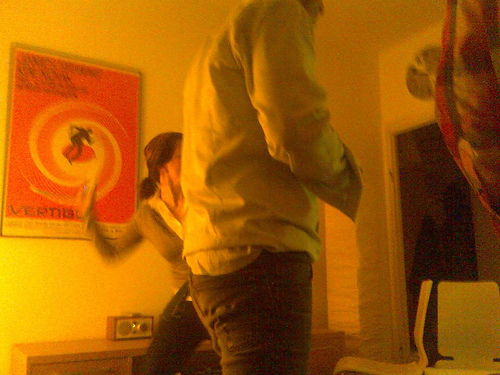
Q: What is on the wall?
A: Poster.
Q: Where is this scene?
A: Living room.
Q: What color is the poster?
A: Orange.